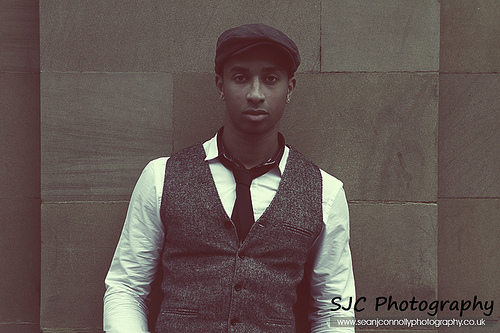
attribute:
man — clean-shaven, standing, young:
[101, 20, 362, 332]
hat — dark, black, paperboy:
[212, 22, 302, 74]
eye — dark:
[263, 73, 279, 87]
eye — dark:
[230, 73, 248, 85]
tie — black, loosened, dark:
[218, 155, 275, 239]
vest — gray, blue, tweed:
[158, 144, 326, 328]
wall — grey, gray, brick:
[39, 1, 499, 331]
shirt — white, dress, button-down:
[103, 136, 361, 332]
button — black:
[237, 248, 247, 260]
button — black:
[232, 280, 246, 293]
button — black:
[229, 315, 240, 327]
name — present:
[328, 293, 496, 313]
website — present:
[332, 317, 489, 329]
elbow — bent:
[100, 273, 153, 302]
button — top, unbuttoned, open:
[222, 216, 236, 230]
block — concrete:
[42, 73, 177, 201]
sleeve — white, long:
[101, 161, 162, 331]